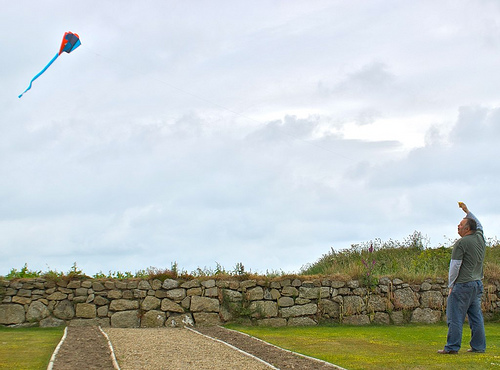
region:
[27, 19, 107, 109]
the kite is flying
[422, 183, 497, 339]
the man is looking up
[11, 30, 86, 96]
kite with a tail in the air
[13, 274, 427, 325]
short stone wall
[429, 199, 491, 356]
man holding onto a kite string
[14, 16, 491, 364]
a man flying a kite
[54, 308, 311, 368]
rock path to a stone wall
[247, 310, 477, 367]
bright green trimmed grass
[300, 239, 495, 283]
mound with grass and weeds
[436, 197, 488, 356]
man with two shirts on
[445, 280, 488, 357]
larger sized blue jeans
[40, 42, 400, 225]
light cloudy sky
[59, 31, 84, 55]
blue and red kite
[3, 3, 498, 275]
cloud cover in sky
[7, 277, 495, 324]
wall of gray stones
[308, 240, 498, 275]
mound of tall grass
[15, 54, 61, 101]
blue tail of kite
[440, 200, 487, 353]
man with arm raised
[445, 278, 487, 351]
blue jeans on legs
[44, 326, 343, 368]
three rows of gravel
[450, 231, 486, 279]
short sleeved green shirt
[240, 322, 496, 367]
green grass on ground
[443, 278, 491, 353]
a man's blue jean pants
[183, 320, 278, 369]
a long white line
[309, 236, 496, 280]
a section of green tall grass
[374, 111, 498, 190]
a section of white clouds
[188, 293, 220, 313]
a large gray stone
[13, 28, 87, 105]
a colorful kite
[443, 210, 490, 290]
a man's green and white shirt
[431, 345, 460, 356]
a man's brown shoe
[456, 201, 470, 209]
the hand of a man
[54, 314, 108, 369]
an area of brown dirt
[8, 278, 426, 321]
short wall made of stones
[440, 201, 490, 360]
man wearing jeans and a longsleeve shirt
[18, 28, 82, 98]
kite with a blue tail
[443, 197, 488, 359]
man flying a kite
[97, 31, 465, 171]
blue and white sky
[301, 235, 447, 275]
mound of grass on top of the stone wall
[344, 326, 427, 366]
green grass near the man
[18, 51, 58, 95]
blue tail of a kite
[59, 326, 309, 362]
light brown and dark brown stones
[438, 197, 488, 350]
man holding his arm above his head to fly a kite